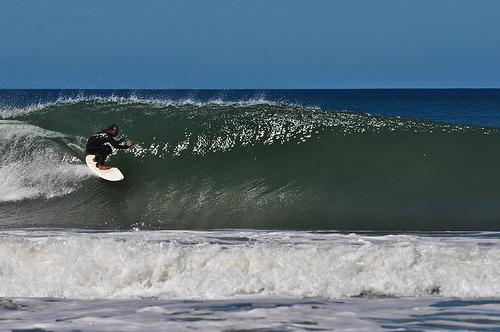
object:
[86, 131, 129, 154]
wetsuit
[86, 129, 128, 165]
clothes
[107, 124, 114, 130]
hair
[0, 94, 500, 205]
wave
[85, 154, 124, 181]
board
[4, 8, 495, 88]
sky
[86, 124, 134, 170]
man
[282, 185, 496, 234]
water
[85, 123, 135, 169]
surfer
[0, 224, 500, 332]
wave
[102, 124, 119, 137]
head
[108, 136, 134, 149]
arm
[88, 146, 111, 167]
leg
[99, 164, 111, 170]
feet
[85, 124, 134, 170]
person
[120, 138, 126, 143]
hand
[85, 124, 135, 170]
people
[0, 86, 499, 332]
ocean